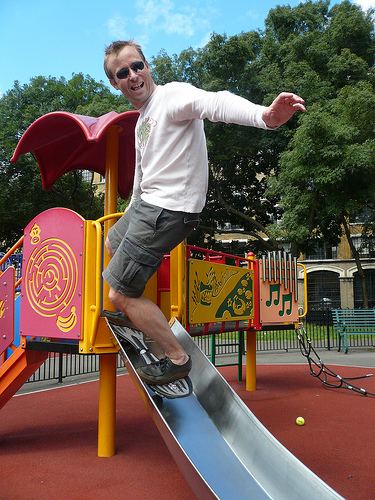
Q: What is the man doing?
A: Skateboarding.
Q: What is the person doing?
A: Skateboarding.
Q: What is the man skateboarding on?
A: A sliding board.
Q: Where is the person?
A: A playground.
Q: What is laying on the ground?
A: A tennis ball.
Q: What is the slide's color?
A: Silver.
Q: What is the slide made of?
A: Metal.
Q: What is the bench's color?
A: Green.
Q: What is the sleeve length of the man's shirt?
A: Long.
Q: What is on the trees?
A: Green leaves.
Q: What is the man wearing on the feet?
A: Black shoes.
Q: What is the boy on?
A: Slide.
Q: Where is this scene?
A: Playground.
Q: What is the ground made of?
A: Rubber.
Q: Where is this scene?
A: Playground.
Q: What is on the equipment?
A: Art.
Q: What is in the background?
A: Trees.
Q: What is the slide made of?
A: Steel.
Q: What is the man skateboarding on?
A: A slide.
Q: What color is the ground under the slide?
A: Red.